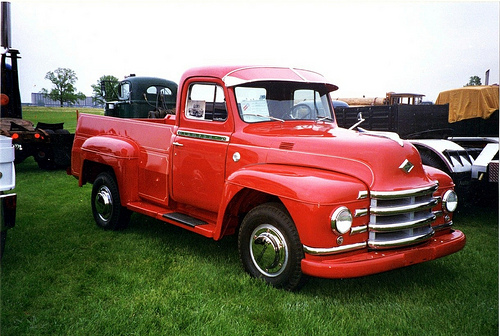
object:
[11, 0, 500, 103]
sky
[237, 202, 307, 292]
tire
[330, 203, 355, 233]
headlight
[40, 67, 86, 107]
tree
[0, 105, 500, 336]
field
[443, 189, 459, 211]
headlight